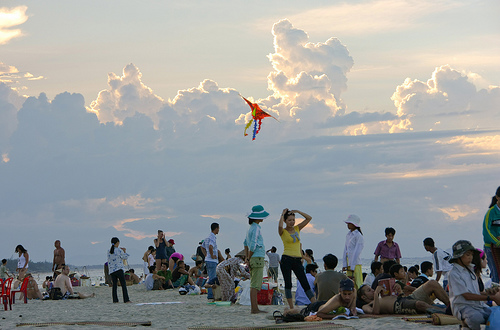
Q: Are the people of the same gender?
A: No, they are both male and female.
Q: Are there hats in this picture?
A: Yes, there is a hat.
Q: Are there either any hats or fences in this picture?
A: Yes, there is a hat.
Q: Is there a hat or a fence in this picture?
A: Yes, there is a hat.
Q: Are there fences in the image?
A: No, there are no fences.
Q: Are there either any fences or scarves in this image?
A: No, there are no fences or scarves.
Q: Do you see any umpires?
A: No, there are no umpires.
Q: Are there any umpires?
A: No, there are no umpires.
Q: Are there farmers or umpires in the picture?
A: No, there are no umpires or farmers.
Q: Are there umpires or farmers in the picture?
A: No, there are no umpires or farmers.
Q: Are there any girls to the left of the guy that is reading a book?
A: Yes, there is a girl to the left of the guy.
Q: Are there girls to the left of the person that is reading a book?
A: Yes, there is a girl to the left of the guy.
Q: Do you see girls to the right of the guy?
A: No, the girl is to the left of the guy.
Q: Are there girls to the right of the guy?
A: No, the girl is to the left of the guy.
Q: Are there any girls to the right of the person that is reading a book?
A: No, the girl is to the left of the guy.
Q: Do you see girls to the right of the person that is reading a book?
A: No, the girl is to the left of the guy.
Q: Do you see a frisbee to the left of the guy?
A: No, there is a girl to the left of the guy.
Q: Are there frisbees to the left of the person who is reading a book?
A: No, there is a girl to the left of the guy.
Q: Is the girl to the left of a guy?
A: Yes, the girl is to the left of a guy.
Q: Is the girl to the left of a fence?
A: No, the girl is to the left of a guy.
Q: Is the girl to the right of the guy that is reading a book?
A: No, the girl is to the left of the guy.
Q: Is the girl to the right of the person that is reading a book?
A: No, the girl is to the left of the guy.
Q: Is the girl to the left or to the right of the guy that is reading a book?
A: The girl is to the left of the guy.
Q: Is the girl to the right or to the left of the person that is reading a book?
A: The girl is to the left of the guy.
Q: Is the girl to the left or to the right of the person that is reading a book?
A: The girl is to the left of the guy.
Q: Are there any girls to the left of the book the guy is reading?
A: Yes, there is a girl to the left of the book.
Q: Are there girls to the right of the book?
A: No, the girl is to the left of the book.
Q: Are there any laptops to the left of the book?
A: No, there is a girl to the left of the book.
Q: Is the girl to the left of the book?
A: Yes, the girl is to the left of the book.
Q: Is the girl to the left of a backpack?
A: No, the girl is to the left of the book.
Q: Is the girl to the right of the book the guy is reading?
A: No, the girl is to the left of the book.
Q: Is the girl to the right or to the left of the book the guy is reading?
A: The girl is to the left of the book.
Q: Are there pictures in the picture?
A: No, there are no pictures.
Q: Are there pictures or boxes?
A: No, there are no pictures or boxes.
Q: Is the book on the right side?
A: Yes, the book is on the right of the image.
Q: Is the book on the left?
A: No, the book is on the right of the image.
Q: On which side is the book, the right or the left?
A: The book is on the right of the image.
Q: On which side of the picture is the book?
A: The book is on the right of the image.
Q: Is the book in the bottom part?
A: Yes, the book is in the bottom of the image.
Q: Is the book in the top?
A: No, the book is in the bottom of the image.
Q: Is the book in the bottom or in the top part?
A: The book is in the bottom of the image.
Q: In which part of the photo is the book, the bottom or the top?
A: The book is in the bottom of the image.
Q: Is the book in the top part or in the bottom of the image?
A: The book is in the bottom of the image.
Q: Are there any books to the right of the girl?
A: Yes, there is a book to the right of the girl.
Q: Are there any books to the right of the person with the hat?
A: Yes, there is a book to the right of the girl.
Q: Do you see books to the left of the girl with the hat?
A: No, the book is to the right of the girl.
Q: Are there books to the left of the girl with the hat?
A: No, the book is to the right of the girl.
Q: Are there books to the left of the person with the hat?
A: No, the book is to the right of the girl.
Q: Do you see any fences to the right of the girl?
A: No, there is a book to the right of the girl.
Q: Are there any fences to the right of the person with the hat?
A: No, there is a book to the right of the girl.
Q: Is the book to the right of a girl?
A: Yes, the book is to the right of a girl.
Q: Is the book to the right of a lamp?
A: No, the book is to the right of a girl.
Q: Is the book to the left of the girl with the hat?
A: No, the book is to the right of the girl.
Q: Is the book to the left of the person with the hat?
A: No, the book is to the right of the girl.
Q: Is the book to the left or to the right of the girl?
A: The book is to the right of the girl.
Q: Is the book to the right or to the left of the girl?
A: The book is to the right of the girl.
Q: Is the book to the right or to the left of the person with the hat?
A: The book is to the right of the girl.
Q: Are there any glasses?
A: No, there are no glasses.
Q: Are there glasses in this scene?
A: No, there are no glasses.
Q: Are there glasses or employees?
A: No, there are no glasses or employees.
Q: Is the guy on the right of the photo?
A: Yes, the guy is on the right of the image.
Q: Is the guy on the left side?
A: No, the guy is on the right of the image.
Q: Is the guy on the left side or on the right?
A: The guy is on the right of the image.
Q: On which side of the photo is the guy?
A: The guy is on the right of the image.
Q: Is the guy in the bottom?
A: Yes, the guy is in the bottom of the image.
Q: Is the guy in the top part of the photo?
A: No, the guy is in the bottom of the image.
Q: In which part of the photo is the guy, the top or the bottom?
A: The guy is in the bottom of the image.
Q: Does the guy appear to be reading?
A: Yes, the guy is reading.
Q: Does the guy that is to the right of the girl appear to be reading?
A: Yes, the guy is reading.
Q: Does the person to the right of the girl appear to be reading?
A: Yes, the guy is reading.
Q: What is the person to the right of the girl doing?
A: The guy is reading.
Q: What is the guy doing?
A: The guy is reading.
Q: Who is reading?
A: The guy is reading.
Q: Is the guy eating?
A: No, the guy is reading.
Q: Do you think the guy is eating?
A: No, the guy is reading.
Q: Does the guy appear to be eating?
A: No, the guy is reading.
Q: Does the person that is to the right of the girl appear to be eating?
A: No, the guy is reading.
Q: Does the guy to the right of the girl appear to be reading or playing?
A: The guy is reading.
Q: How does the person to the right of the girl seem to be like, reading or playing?
A: The guy is reading.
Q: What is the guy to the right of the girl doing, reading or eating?
A: The guy is reading.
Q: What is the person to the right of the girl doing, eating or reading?
A: The guy is reading.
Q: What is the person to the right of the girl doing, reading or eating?
A: The guy is reading.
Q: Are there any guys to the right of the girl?
A: Yes, there is a guy to the right of the girl.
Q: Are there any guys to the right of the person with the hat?
A: Yes, there is a guy to the right of the girl.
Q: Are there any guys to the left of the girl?
A: No, the guy is to the right of the girl.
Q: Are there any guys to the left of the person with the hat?
A: No, the guy is to the right of the girl.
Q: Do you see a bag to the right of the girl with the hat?
A: No, there is a guy to the right of the girl.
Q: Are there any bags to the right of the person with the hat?
A: No, there is a guy to the right of the girl.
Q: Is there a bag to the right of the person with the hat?
A: No, there is a guy to the right of the girl.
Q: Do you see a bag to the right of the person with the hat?
A: No, there is a guy to the right of the girl.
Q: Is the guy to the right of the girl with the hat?
A: Yes, the guy is to the right of the girl.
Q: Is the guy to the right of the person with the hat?
A: Yes, the guy is to the right of the girl.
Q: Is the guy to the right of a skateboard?
A: No, the guy is to the right of the girl.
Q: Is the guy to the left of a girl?
A: No, the guy is to the right of a girl.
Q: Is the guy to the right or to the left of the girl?
A: The guy is to the right of the girl.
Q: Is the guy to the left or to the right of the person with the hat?
A: The guy is to the right of the girl.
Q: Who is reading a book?
A: The guy is reading a book.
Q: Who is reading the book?
A: The guy is reading a book.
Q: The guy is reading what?
A: The guy is reading a book.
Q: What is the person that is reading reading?
A: The guy is reading a book.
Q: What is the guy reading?
A: The guy is reading a book.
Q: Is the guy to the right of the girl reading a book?
A: Yes, the guy is reading a book.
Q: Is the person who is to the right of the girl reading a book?
A: Yes, the guy is reading a book.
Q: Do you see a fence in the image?
A: No, there are no fences.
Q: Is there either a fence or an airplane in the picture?
A: No, there are no fences or airplanes.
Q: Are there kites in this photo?
A: Yes, there is a kite.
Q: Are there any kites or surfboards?
A: Yes, there is a kite.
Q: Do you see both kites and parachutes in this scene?
A: No, there is a kite but no parachutes.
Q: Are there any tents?
A: No, there are no tents.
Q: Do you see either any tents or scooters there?
A: No, there are no tents or scooters.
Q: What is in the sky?
A: The kite is in the sky.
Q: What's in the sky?
A: The kite is in the sky.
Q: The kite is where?
A: The kite is in the sky.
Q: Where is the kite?
A: The kite is in the sky.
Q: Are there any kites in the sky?
A: Yes, there is a kite in the sky.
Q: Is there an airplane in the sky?
A: No, there is a kite in the sky.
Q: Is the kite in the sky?
A: Yes, the kite is in the sky.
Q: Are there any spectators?
A: No, there are no spectators.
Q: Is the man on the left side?
A: Yes, the man is on the left of the image.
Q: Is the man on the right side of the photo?
A: No, the man is on the left of the image.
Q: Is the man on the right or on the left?
A: The man is on the left of the image.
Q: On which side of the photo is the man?
A: The man is on the left of the image.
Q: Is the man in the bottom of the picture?
A: Yes, the man is in the bottom of the image.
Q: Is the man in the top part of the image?
A: No, the man is in the bottom of the image.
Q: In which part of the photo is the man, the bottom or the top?
A: The man is in the bottom of the image.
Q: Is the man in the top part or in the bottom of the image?
A: The man is in the bottom of the image.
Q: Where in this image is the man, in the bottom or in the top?
A: The man is in the bottom of the image.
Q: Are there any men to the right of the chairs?
A: Yes, there is a man to the right of the chairs.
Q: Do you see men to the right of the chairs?
A: Yes, there is a man to the right of the chairs.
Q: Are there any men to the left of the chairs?
A: No, the man is to the right of the chairs.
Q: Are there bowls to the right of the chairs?
A: No, there is a man to the right of the chairs.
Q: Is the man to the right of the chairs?
A: Yes, the man is to the right of the chairs.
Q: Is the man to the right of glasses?
A: No, the man is to the right of the chairs.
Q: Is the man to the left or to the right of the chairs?
A: The man is to the right of the chairs.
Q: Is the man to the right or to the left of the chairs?
A: The man is to the right of the chairs.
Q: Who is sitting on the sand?
A: The man is sitting on the sand.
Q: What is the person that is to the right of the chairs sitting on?
A: The man is sitting on the sand.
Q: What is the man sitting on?
A: The man is sitting on the sand.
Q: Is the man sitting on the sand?
A: Yes, the man is sitting on the sand.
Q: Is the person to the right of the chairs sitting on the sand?
A: Yes, the man is sitting on the sand.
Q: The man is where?
A: The man is on the sand.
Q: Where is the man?
A: The man is on the sand.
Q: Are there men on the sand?
A: Yes, there is a man on the sand.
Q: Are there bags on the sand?
A: No, there is a man on the sand.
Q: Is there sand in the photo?
A: Yes, there is sand.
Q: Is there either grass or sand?
A: Yes, there is sand.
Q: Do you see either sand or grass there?
A: Yes, there is sand.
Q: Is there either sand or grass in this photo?
A: Yes, there is sand.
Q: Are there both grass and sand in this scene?
A: No, there is sand but no grass.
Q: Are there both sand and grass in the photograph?
A: No, there is sand but no grass.